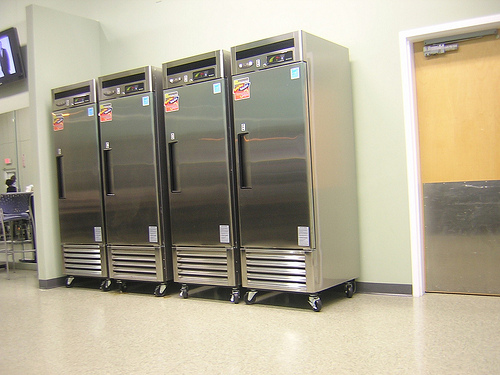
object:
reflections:
[276, 321, 313, 373]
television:
[0, 28, 25, 86]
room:
[1, 0, 500, 375]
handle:
[237, 131, 252, 189]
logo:
[290, 67, 300, 79]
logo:
[213, 82, 221, 94]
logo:
[142, 96, 150, 107]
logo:
[88, 107, 95, 116]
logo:
[234, 77, 251, 101]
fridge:
[50, 31, 362, 293]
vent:
[63, 244, 100, 275]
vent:
[110, 246, 158, 281]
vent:
[176, 247, 228, 280]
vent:
[247, 248, 305, 290]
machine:
[51, 30, 360, 293]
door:
[232, 61, 316, 250]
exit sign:
[5, 158, 11, 164]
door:
[7, 171, 16, 191]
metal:
[423, 181, 500, 294]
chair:
[0, 192, 38, 279]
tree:
[241, 282, 365, 304]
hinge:
[422, 42, 458, 56]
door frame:
[398, 13, 500, 298]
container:
[229, 29, 359, 294]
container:
[161, 49, 241, 287]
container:
[96, 65, 172, 282]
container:
[51, 79, 109, 279]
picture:
[233, 77, 250, 101]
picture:
[164, 92, 180, 112]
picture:
[98, 103, 112, 123]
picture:
[53, 114, 63, 131]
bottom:
[422, 179, 500, 295]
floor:
[0, 241, 500, 375]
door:
[409, 33, 500, 295]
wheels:
[64, 278, 354, 312]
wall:
[3, 0, 499, 286]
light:
[284, 332, 301, 352]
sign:
[5, 158, 11, 164]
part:
[262, 145, 271, 165]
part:
[306, 300, 315, 303]